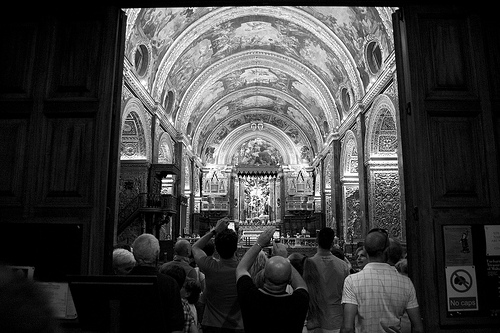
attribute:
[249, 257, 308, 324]
back — man's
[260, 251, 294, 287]
head — bald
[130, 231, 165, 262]
hair — gray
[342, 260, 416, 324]
shirt — short sleeve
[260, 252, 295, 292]
head — bald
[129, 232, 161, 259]
hair — white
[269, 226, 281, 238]
phone — cell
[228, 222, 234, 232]
phone — cell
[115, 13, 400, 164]
ceiling — beautiful, arched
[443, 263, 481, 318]
sign — white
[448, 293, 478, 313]
writing — white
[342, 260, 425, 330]
shirt — white, checkered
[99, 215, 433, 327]
people — facing away